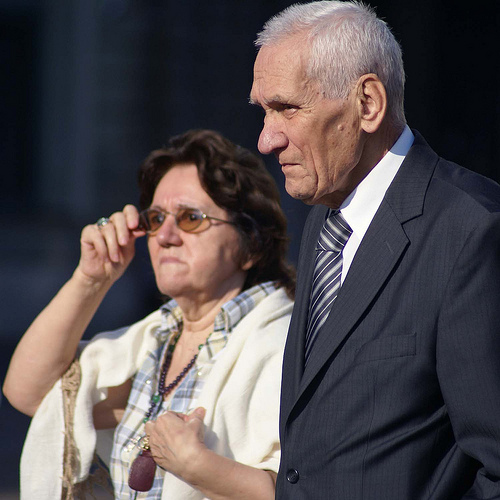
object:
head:
[248, 0, 405, 208]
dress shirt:
[326, 124, 415, 292]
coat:
[18, 281, 299, 500]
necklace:
[142, 327, 217, 423]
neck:
[172, 271, 251, 330]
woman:
[0, 129, 297, 500]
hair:
[252, 0, 407, 135]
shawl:
[18, 287, 295, 500]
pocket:
[353, 331, 417, 367]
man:
[247, 0, 500, 500]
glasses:
[139, 207, 237, 236]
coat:
[272, 129, 499, 498]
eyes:
[185, 212, 199, 224]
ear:
[354, 74, 386, 134]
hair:
[139, 128, 297, 300]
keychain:
[127, 444, 156, 491]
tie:
[300, 212, 354, 369]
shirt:
[109, 280, 275, 500]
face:
[146, 165, 242, 295]